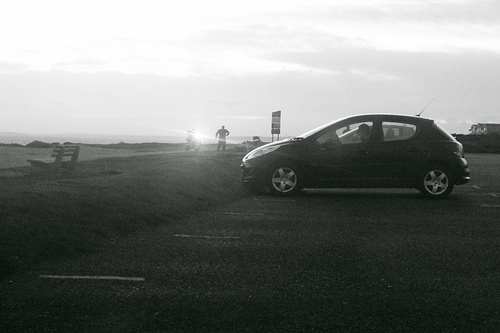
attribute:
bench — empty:
[24, 140, 85, 177]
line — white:
[27, 262, 185, 294]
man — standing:
[191, 116, 245, 168]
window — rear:
[380, 120, 416, 144]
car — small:
[239, 111, 471, 200]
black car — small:
[241, 114, 472, 203]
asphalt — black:
[0, 152, 499, 331]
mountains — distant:
[1, 133, 106, 156]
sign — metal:
[267, 109, 281, 139]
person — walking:
[216, 117, 242, 157]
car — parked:
[216, 105, 486, 211]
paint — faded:
[59, 264, 147, 305]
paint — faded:
[188, 207, 238, 251]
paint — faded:
[204, 201, 278, 226]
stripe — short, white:
[40, 270, 146, 282]